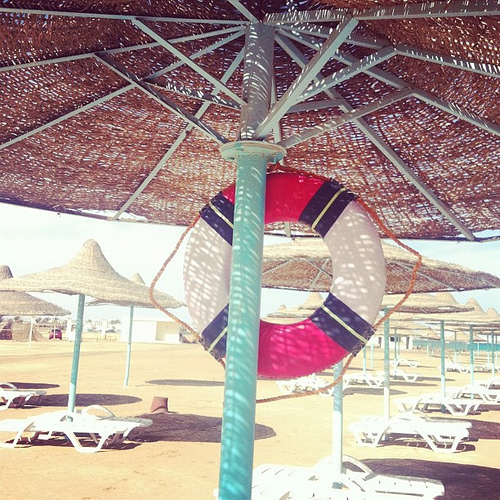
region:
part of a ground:
[271, 428, 292, 466]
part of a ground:
[286, 417, 308, 456]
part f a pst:
[231, 368, 271, 441]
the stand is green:
[213, 156, 253, 497]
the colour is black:
[301, 181, 345, 232]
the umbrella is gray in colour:
[1, 242, 159, 308]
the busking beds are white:
[3, 419, 142, 442]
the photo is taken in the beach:
[15, 117, 499, 493]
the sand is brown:
[39, 458, 184, 499]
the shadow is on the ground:
[413, 455, 480, 498]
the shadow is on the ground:
[151, 409, 258, 447]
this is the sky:
[21, 210, 70, 263]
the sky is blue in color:
[15, 218, 41, 245]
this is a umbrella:
[84, 49, 183, 169]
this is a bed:
[68, 415, 102, 428]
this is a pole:
[221, 185, 266, 495]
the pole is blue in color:
[228, 205, 258, 270]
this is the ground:
[127, 446, 213, 489]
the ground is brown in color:
[152, 430, 183, 490]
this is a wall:
[136, 321, 161, 333]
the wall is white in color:
[137, 320, 147, 335]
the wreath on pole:
[185, 167, 390, 382]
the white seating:
[0, 334, 497, 499]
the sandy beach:
[0, 342, 497, 499]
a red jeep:
[47, 320, 65, 341]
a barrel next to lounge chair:
[147, 392, 171, 412]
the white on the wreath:
[178, 199, 389, 337]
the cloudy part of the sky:
[388, 232, 498, 314]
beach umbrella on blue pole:
[1, 238, 186, 413]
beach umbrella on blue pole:
[86, 270, 184, 386]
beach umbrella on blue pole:
[261, 234, 480, 468]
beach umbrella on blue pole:
[386, 290, 475, 427]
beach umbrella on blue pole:
[439, 299, 489, 371]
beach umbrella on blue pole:
[485, 313, 494, 369]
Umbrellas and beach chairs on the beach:
[3, 62, 495, 497]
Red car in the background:
[47, 325, 62, 339]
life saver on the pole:
[146, 154, 382, 382]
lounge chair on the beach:
[244, 442, 451, 499]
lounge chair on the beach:
[10, 402, 142, 454]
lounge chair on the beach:
[355, 408, 473, 449]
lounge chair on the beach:
[402, 383, 493, 410]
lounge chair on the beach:
[344, 362, 417, 393]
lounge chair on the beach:
[1, 376, 42, 403]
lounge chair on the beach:
[371, 362, 426, 381]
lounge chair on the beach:
[445, 377, 499, 396]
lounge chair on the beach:
[384, 353, 424, 367]